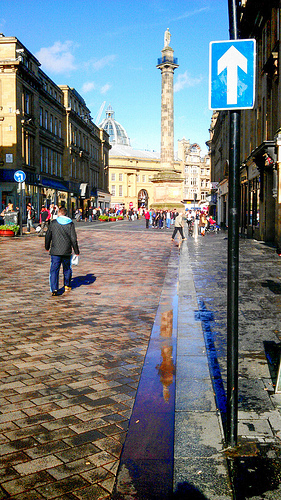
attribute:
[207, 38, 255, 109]
sign — blue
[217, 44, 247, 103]
arrow — white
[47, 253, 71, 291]
jeans — blue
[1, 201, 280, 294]
many people — moving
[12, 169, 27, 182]
sign — blue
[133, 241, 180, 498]
soggy trough — wet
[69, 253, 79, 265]
bag — white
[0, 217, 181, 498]
street — paved, cobblestone, brick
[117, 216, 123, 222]
planters — large 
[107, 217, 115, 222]
planters — large 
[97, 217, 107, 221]
planters — large 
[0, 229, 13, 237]
planters — large 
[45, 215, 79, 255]
jacket — black, diamond pattern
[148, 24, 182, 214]
monument — Beautiful, tall 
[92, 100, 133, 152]
dome — white, glass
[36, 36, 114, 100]
clouds — white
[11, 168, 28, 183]
round sign — blue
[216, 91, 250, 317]
post — black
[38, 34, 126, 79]
clouds — whispy, white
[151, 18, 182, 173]
tower — white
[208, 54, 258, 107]
sign — blue, white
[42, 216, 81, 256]
jacket — black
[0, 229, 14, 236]
planter — full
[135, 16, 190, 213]
tower — reflected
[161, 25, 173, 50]
statue — large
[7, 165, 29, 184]
sign — round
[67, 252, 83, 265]
bag — white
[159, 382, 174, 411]
sculpture — reflected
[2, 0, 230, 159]
sky —  blue